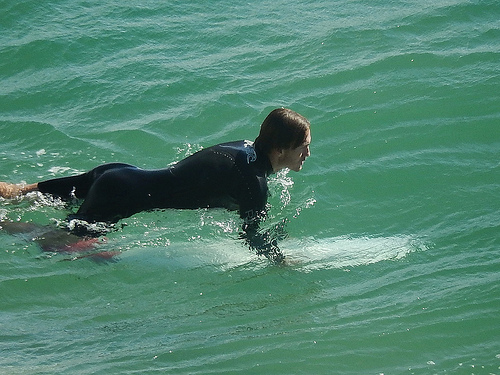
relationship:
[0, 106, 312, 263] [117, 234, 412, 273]
man riding surfboard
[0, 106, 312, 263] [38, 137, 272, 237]
man has wetsuit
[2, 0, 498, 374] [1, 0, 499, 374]
ocean has ripples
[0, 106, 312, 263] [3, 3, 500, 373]
man through water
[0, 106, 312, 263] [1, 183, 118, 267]
man has legs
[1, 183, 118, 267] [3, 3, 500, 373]
legs kicking water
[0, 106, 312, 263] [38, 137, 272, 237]
man wearing wetsuit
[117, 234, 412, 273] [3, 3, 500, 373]
surfboard under water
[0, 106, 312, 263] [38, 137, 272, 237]
man in wetsuit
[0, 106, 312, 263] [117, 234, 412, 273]
man holds surfboard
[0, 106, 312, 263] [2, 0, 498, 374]
man in ocean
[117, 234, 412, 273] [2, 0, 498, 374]
surfboard in ocean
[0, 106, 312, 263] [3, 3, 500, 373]
man in water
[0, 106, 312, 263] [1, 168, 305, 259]
man creates waves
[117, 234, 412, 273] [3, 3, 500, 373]
surfboard in water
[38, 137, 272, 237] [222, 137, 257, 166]
wetsuit has design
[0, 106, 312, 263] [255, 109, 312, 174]
man has head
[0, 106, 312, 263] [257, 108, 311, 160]
man has hair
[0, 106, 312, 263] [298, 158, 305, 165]
man has mouth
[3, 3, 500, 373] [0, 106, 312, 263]
water around man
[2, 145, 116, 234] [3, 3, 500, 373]
foam in water